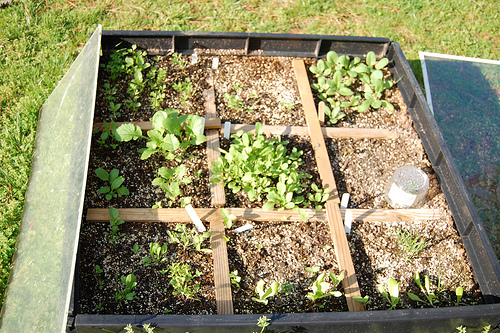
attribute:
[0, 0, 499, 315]
grass — short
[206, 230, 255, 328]
bar — wooden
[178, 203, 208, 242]
label — white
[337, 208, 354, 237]
label — white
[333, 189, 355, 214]
label — white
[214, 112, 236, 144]
label — white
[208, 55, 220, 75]
label — white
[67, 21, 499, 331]
bed — nursery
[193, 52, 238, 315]
wood bar — wooden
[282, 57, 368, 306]
wood bar — wooden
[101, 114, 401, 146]
wood bar — wooden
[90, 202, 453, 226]
wood bar — wooden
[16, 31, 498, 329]
box — black, big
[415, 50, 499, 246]
window — clear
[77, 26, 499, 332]
box — big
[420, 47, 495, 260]
wire frame — fallen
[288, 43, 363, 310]
bar — wooden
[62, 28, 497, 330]
frame — black, plastic, cold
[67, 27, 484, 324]
tub — plastic, perforated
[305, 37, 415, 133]
corner — top